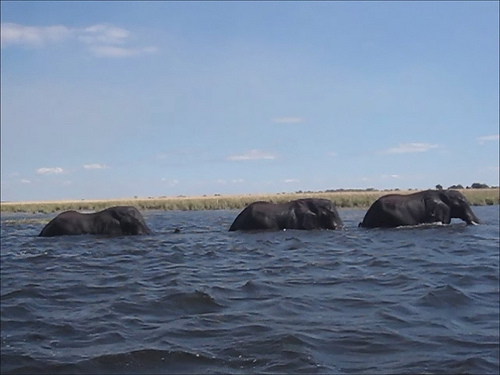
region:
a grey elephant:
[373, 193, 473, 225]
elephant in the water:
[46, 210, 146, 234]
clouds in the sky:
[229, 152, 296, 166]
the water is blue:
[140, 262, 331, 342]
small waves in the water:
[106, 336, 208, 366]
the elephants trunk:
[135, 218, 170, 237]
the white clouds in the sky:
[32, 160, 112, 180]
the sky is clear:
[172, 47, 303, 102]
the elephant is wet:
[236, 188, 346, 234]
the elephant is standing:
[355, 189, 475, 234]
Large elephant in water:
[362, 188, 482, 229]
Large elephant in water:
[230, 194, 344, 236]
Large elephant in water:
[36, 205, 183, 240]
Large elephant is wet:
[357, 190, 485, 227]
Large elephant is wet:
[228, 198, 344, 232]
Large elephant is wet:
[35, 205, 182, 237]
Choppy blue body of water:
[0, 206, 498, 373]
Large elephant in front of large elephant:
[358, 188, 476, 229]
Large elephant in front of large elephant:
[232, 194, 339, 229]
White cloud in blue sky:
[222, 146, 274, 161]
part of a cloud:
[260, 87, 300, 130]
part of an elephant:
[282, 200, 332, 263]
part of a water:
[380, 235, 418, 285]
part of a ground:
[186, 188, 229, 251]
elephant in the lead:
[355, 189, 480, 229]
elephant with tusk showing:
[360, 189, 479, 229]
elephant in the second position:
[231, 197, 342, 232]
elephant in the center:
[229, 197, 340, 233]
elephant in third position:
[40, 207, 181, 237]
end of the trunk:
[171, 222, 183, 238]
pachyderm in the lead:
[356, 188, 478, 231]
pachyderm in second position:
[225, 200, 341, 236]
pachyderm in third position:
[37, 207, 180, 239]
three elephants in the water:
[38, 190, 480, 235]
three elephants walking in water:
[22, 182, 488, 355]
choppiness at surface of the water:
[16, 240, 477, 364]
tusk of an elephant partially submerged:
[462, 216, 484, 233]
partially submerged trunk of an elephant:
[138, 215, 189, 243]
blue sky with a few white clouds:
[104, 0, 428, 183]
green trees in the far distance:
[421, 180, 493, 193]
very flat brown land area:
[0, 185, 294, 208]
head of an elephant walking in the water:
[287, 189, 352, 238]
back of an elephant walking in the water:
[365, 190, 448, 211]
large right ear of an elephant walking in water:
[93, 198, 137, 243]